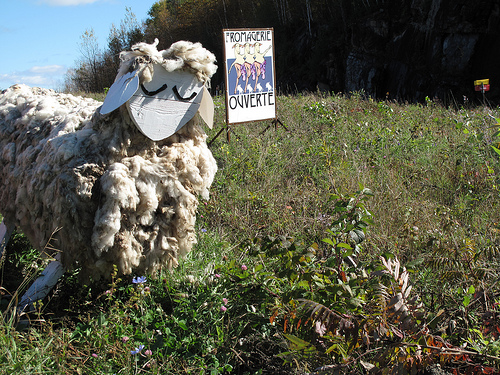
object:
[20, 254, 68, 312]
legs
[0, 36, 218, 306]
lamb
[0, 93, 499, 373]
vegetation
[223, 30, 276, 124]
sign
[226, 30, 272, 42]
fromagerie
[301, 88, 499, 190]
bush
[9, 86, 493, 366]
field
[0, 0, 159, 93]
sky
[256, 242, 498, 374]
leaves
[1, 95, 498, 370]
floor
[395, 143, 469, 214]
grass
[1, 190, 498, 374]
growth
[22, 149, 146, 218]
fur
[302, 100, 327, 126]
weed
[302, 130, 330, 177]
weed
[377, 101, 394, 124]
weed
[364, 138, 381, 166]
weed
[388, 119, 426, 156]
weed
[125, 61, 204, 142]
box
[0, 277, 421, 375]
grass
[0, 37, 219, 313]
fake sheep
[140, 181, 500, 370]
bushes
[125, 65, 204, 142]
face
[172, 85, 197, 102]
eye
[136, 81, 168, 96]
eye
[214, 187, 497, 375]
green vegetation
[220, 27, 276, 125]
signboard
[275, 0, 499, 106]
forest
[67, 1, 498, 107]
trees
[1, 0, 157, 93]
clouds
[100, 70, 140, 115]
ear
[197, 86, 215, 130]
ear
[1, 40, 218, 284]
wool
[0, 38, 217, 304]
scarecrow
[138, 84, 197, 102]
paintings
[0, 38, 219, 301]
body